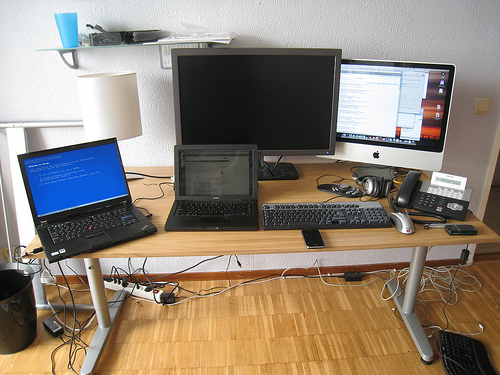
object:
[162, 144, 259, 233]
notebook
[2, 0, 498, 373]
office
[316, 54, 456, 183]
computer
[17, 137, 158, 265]
laptop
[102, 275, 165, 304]
power strip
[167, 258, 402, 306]
wires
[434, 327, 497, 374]
keyboard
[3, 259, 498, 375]
floor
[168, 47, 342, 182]
monitor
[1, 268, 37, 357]
basket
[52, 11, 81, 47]
glass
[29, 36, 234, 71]
shelf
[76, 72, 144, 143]
lampshade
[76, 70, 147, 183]
lamp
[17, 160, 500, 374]
desk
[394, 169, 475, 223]
phone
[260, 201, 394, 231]
keyboard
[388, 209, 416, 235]
mouse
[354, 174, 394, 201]
headphone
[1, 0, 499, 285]
wall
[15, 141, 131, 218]
screen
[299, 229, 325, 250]
iphone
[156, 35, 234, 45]
paper